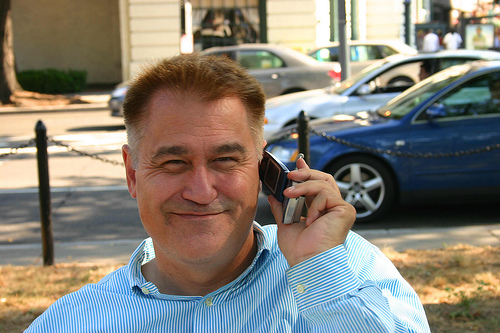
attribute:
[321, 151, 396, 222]
black tire — round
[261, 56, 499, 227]
car — blue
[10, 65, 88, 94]
hedges — green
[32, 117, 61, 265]
pole — metal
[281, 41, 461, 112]
car — white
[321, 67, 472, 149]
car — blue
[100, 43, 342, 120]
car — gray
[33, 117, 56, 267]
pole — Black 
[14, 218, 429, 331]
shirt — blue, striped, white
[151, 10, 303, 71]
window — large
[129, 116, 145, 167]
hair — gray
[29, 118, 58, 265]
post — black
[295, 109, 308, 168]
post — black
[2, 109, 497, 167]
chain — metal